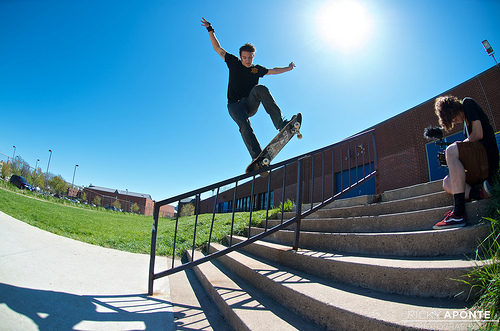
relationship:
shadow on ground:
[0, 276, 180, 330] [4, 240, 153, 329]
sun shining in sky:
[298, 0, 391, 62] [1, 1, 499, 203]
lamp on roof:
[479, 32, 499, 68] [408, 45, 496, 112]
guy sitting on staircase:
[199, 15, 299, 178] [238, 171, 497, 328]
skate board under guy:
[244, 111, 302, 176] [190, 7, 317, 178]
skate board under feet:
[244, 111, 302, 176] [246, 113, 300, 181]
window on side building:
[331, 163, 374, 203] [167, 51, 497, 211]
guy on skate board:
[199, 15, 299, 178] [244, 111, 302, 182]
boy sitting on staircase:
[433, 94, 499, 229] [238, 171, 497, 328]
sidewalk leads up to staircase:
[0, 210, 178, 329] [238, 171, 497, 328]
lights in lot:
[35, 141, 89, 176] [16, 171, 144, 205]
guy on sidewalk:
[199, 15, 299, 178] [1, 245, 201, 330]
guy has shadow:
[199, 15, 299, 178] [0, 276, 180, 327]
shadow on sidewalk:
[0, 276, 180, 327] [1, 245, 201, 330]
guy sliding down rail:
[199, 15, 299, 178] [148, 123, 384, 303]